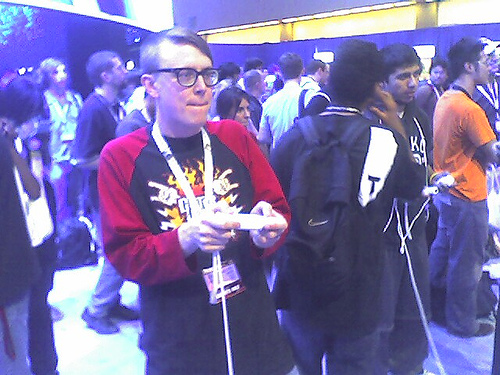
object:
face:
[169, 42, 222, 142]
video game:
[193, 202, 305, 258]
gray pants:
[430, 186, 490, 341]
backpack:
[288, 114, 373, 304]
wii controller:
[218, 212, 265, 237]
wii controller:
[423, 173, 456, 194]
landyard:
[475, 85, 498, 106]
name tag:
[483, 112, 497, 129]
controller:
[199, 213, 269, 233]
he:
[94, 22, 296, 372]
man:
[68, 51, 139, 335]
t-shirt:
[97, 117, 295, 373]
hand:
[189, 202, 240, 252]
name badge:
[201, 261, 246, 305]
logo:
[145, 165, 243, 225]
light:
[409, 0, 440, 32]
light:
[273, 21, 300, 44]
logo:
[306, 215, 331, 227]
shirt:
[263, 111, 421, 291]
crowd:
[15, 24, 497, 350]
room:
[3, 3, 491, 373]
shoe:
[81, 305, 129, 336]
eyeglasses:
[472, 55, 500, 68]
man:
[96, 26, 302, 372]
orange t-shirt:
[431, 86, 499, 201]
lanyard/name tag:
[145, 125, 242, 303]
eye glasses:
[146, 65, 226, 87]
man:
[420, 35, 498, 324]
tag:
[207, 259, 250, 306]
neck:
[154, 109, 203, 142]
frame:
[152, 65, 220, 87]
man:
[269, 39, 425, 373]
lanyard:
[148, 118, 226, 262]